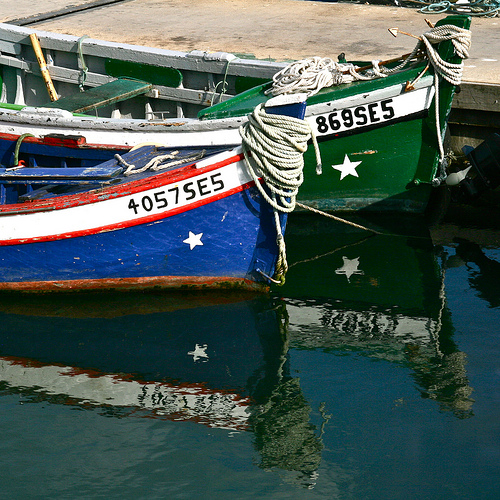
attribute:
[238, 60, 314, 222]
rope — wrapped